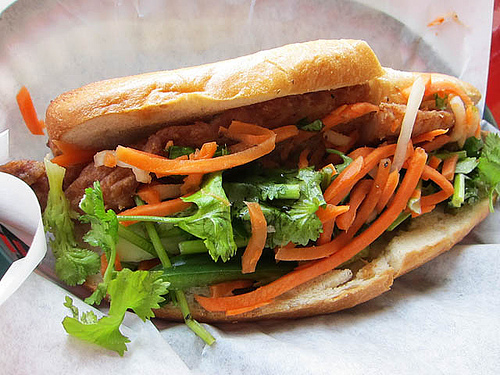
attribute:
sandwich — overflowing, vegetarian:
[36, 31, 497, 334]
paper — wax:
[2, 3, 497, 372]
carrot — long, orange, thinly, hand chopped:
[112, 119, 283, 177]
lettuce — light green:
[61, 266, 172, 356]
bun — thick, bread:
[42, 34, 385, 145]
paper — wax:
[336, 1, 491, 94]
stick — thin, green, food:
[137, 220, 218, 350]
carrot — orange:
[323, 157, 365, 239]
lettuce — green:
[276, 167, 326, 249]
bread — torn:
[303, 232, 433, 318]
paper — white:
[384, 269, 497, 372]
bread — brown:
[41, 33, 382, 142]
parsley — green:
[60, 180, 169, 356]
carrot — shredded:
[320, 146, 430, 271]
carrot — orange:
[334, 140, 432, 260]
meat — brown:
[65, 162, 136, 210]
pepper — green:
[148, 257, 282, 292]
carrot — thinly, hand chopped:
[193, 230, 395, 314]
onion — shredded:
[387, 70, 434, 172]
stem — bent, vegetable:
[172, 290, 218, 348]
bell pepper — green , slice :
[134, 254, 234, 288]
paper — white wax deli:
[227, 335, 389, 373]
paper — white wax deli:
[276, 325, 478, 373]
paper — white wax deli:
[264, 335, 478, 373]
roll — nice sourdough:
[52, 34, 478, 311]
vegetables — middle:
[144, 142, 435, 241]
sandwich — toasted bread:
[56, 46, 381, 120]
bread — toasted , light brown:
[75, 62, 349, 98]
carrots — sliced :
[206, 233, 341, 300]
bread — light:
[53, 45, 387, 118]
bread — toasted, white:
[51, 48, 388, 138]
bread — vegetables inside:
[55, 48, 387, 127]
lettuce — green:
[162, 194, 229, 245]